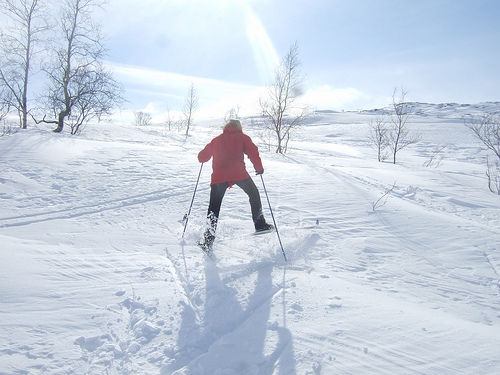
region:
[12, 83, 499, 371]
snow on the ground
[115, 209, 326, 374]
ski tracks in the snow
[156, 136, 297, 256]
a set of ski poles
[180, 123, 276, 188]
person wearing a red jacket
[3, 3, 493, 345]
a bright and clear day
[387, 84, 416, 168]
bare tree on the snowy slope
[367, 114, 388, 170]
bare tree on the snowy slope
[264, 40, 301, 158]
bare tree on the snowy slope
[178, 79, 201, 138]
bare tree on the snowy slope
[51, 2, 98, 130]
bare tree on the snowy slope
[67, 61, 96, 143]
bare tree on the snowy slope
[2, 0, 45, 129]
bare tree on the snowy slope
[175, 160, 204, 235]
long pole for the man skiing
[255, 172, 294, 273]
long pole for the man skiing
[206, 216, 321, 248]
long ski for the man skiing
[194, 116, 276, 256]
person in the snow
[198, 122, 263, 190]
a red jacket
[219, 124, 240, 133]
hood of a jacket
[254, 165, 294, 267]
right ski pole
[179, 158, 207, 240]
left ski pole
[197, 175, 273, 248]
pants of a person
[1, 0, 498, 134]
light blue colored sky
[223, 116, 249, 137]
head of a person in the snow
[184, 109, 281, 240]
skier with red jacket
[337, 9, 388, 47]
white clouds in blue sky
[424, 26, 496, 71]
white clouds in blue sky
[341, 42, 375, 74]
white clouds in blue sky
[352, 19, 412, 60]
white clouds in blue sky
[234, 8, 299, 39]
white clouds in blue sky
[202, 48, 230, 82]
white clouds in blue sky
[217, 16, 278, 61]
white clouds in blue sky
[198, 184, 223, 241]
The left foot of the man.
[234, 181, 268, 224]
The right foot of the man.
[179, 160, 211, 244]
The left ski pole.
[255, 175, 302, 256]
The right ski pole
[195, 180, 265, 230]
The man is wearing a black pant.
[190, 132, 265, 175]
The man is wearing a red jacket.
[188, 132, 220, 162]
The left hand of the man.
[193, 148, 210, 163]
The elbow of the man.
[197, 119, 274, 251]
A person in a red coat and black pants.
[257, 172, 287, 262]
A person's right ski pole.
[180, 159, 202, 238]
A left ski pole.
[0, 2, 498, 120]
A blue and white sky.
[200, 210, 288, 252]
A person wearing skis in the snow.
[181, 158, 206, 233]
A person holding on to a pole.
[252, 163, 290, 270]
A person holding on to the pole.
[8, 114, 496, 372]
The ground covered in snow.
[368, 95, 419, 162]
The trees have no leafs.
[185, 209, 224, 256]
Snow is on the leg of the person.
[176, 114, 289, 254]
A person cross country sking in the snow.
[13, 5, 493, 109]
The sky is blue with a few white clouds.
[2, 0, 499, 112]
The sky is blue with a few white clouds.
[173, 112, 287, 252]
person is skiing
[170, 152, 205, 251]
ski pole is black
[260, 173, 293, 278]
ski pole is black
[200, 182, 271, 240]
pants are black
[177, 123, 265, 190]
person wearing a red jacket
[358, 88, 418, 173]
the trees are barren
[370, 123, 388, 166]
the tree is small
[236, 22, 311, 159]
the tree is bare